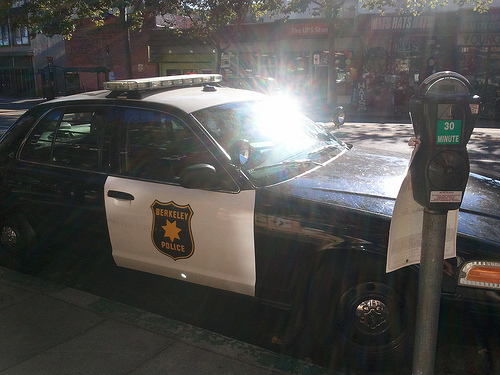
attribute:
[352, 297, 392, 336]
hubcaps — metal, silver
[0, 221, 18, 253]
hubcaps — silver, metal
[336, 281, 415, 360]
rim — black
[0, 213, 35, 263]
rim — black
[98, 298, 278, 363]
green paint — worn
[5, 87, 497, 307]
car — police car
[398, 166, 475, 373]
pole — gray, metal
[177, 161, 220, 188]
mirror — side view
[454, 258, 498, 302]
orange light — clear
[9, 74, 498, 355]
vehicle — police vehicle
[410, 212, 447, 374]
pole — metal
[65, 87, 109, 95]
bench — wooden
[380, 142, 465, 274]
sign — paper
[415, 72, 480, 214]
parking meter — metal, gray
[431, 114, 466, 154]
sign — green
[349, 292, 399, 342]
rim — silver, black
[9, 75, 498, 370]
car — white, black , parked 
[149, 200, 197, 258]
sticker — gold, black